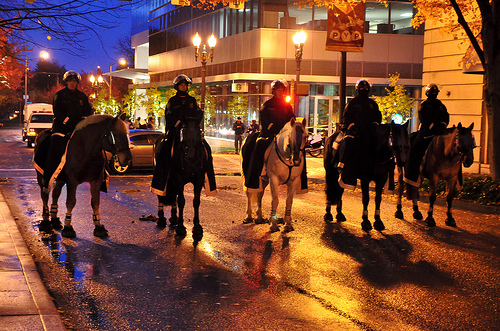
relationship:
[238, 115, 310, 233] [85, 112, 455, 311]
horse on street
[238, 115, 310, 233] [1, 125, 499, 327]
horse on road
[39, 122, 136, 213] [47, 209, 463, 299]
horse walking on street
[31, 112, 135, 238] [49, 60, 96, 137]
horse carrying officers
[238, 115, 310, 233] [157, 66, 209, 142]
horse carrying officers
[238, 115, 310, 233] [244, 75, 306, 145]
horse carrying officers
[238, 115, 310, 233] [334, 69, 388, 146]
horse carrying officers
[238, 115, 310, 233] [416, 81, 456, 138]
horse carrying officers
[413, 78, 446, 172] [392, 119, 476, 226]
police officer riding horse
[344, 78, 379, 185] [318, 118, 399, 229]
police officer riding horse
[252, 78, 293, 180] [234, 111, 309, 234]
police officer riding horse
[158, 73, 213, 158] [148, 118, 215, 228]
officers riding horse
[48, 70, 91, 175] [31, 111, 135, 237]
police officer riding horse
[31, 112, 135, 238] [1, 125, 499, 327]
horse walking on road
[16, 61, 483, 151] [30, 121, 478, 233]
officers sitting on horses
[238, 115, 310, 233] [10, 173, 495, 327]
horse on street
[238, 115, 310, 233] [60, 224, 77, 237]
horse has hoof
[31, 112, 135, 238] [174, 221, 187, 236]
horse has hoof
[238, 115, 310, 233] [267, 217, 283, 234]
horse has hoof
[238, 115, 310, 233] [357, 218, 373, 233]
horse has hoof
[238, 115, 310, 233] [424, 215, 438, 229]
horse has hoof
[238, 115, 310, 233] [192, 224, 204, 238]
horse has hoof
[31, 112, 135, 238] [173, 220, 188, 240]
horse has hoof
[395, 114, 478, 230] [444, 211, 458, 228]
horse has hoof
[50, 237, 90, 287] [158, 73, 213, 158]
water near officers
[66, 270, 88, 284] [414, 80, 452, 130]
water near people.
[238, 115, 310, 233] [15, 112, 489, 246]
horse in line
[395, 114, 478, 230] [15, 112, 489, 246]
horse in line